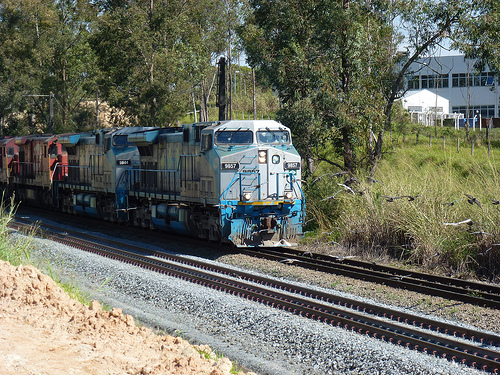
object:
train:
[1, 116, 306, 255]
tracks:
[241, 243, 499, 311]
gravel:
[29, 238, 497, 375]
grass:
[302, 123, 497, 283]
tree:
[237, 0, 393, 194]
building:
[392, 52, 499, 132]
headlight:
[240, 192, 251, 201]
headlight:
[283, 191, 294, 201]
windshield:
[213, 127, 254, 146]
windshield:
[256, 129, 289, 146]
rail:
[6, 157, 176, 195]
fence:
[404, 114, 497, 135]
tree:
[443, 0, 499, 91]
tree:
[85, 0, 235, 135]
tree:
[29, 29, 96, 131]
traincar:
[8, 131, 73, 211]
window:
[440, 78, 450, 86]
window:
[480, 76, 488, 86]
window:
[459, 77, 466, 87]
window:
[419, 78, 427, 89]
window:
[440, 79, 450, 89]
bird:
[462, 191, 485, 208]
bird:
[444, 217, 472, 229]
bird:
[336, 182, 356, 197]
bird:
[386, 193, 409, 205]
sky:
[0, 1, 499, 70]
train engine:
[105, 121, 305, 247]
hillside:
[0, 255, 255, 374]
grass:
[0, 184, 88, 307]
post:
[465, 139, 475, 157]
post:
[455, 137, 462, 155]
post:
[483, 118, 492, 159]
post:
[441, 138, 447, 153]